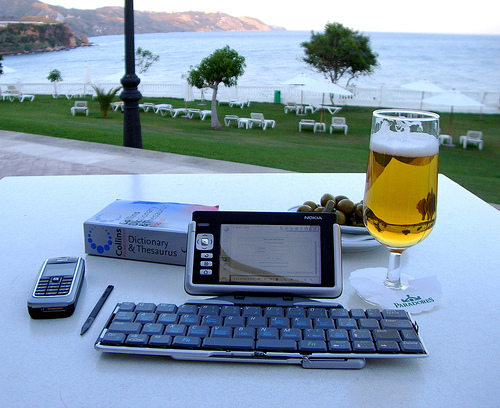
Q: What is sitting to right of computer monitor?
A: Glass.